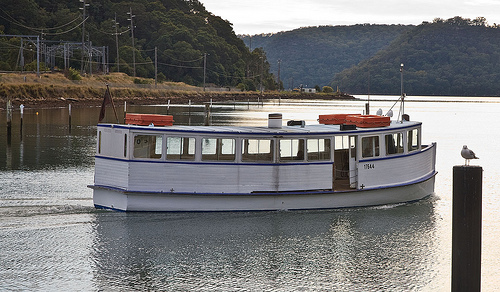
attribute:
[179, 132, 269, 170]
window — glass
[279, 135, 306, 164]
window — glass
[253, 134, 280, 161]
window — glass 